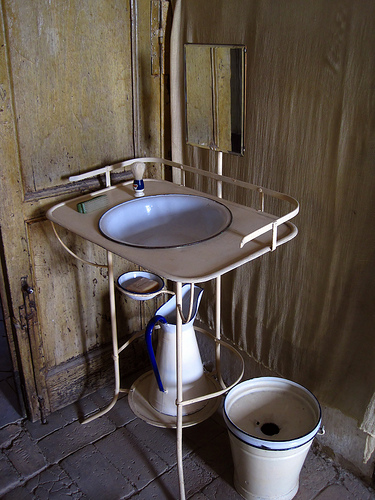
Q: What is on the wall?
A: A mirror.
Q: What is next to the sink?
A: A shaving cream brush.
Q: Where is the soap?
A: Under the sink.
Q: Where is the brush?
A: On the sink.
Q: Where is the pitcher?
A: Under the sink.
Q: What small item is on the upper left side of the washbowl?
A: A shaving brush.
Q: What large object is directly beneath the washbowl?
A: A large pitcher.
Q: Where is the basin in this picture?
A: Right side of the washbowl area.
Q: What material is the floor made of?
A: Brick.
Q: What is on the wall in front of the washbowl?
A: A mirror.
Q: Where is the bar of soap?
A: In the soap dish under washbowl.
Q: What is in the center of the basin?
A: A hole.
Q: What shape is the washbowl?
A: A circle.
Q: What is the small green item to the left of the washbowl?
A: A nail brush.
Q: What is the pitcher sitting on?
A: A plate.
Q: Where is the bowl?
A: Next to the bucket.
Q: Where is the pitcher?
A: Under the sink.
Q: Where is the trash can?
A: Next to the sink.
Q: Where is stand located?
A: With the sink.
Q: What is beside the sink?
A: Worn wood wall.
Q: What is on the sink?
A: A brush.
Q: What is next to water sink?
A: A door.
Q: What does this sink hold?
A: Water.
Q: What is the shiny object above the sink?
A: Mirror.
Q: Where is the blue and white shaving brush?
A: On the sink.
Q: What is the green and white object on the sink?
A: Brush.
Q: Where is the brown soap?
A: In a dish under the sink.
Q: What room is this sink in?
A: Bathroom.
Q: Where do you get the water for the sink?
A: Blue and white pitcher.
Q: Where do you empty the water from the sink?
A: White bucket.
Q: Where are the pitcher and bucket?
A: Floor under the sink.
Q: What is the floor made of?
A: Brick.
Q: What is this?
A: Sink.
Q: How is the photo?
A: Clear.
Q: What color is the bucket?
A: White.